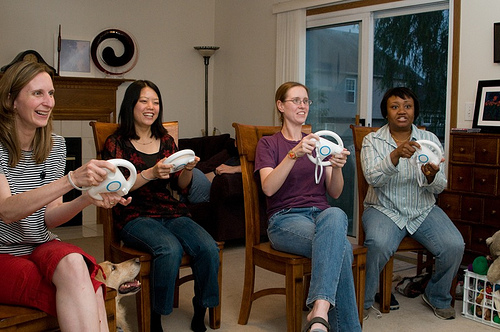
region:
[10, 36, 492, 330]
women are sitting on the chair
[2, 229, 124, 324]
the shorts are red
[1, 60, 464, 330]
Four women playing video games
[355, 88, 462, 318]
Woman holding video game controller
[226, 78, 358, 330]
Woman sitting in chair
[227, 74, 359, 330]
Woman playing video game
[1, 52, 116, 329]
Woman laughing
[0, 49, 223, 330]
Two woman laughing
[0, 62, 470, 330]
Women sitting playing video games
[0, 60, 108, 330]
Woman in striped shirt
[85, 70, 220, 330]
Dog looking at woman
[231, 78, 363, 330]
Woman in purple tee shirt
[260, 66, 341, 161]
the head of a woman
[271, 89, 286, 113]
the ear of a woman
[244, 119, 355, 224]
the arm of a woman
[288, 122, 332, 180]
the hand of a woman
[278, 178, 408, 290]
the legs of a woman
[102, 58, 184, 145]
the hair of a woman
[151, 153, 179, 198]
the fingers of a woman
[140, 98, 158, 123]
the nose of a woman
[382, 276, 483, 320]
the feet of a woman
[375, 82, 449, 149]
the teeth of a woman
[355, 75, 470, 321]
woman in striped shirt sitting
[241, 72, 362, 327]
woman in purple shirt sitting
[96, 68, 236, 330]
woman in red and black sitting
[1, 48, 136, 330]
woman in shorts sitting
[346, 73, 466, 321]
woman in stripes playing game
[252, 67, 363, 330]
woman in purple playing game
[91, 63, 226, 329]
woman in red and black playing game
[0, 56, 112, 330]
woman in shorts playing game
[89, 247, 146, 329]
dog looking up from floor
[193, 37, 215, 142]
tall lamp in corner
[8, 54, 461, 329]
four women playing xbox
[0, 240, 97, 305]
the short pant is red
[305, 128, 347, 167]
a white wheel-shaped game control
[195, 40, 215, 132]
a modern lamp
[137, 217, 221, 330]
she is wearing a blue jeans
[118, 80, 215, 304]
she is smiling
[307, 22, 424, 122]
a house in the background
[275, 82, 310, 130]
the head of the player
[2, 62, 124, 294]
she is happy playing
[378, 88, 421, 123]
she has a short black hair